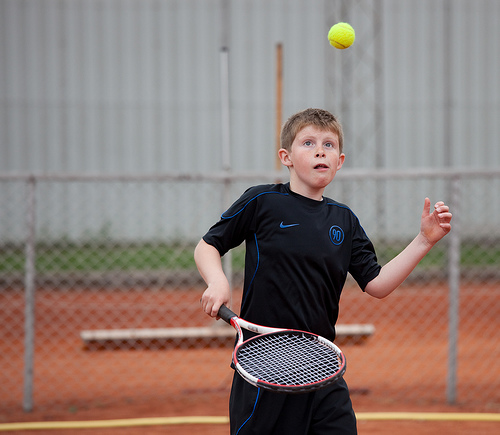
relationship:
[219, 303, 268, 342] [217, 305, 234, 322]
handle has tape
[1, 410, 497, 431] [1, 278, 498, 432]
line on ground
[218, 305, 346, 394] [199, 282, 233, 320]
racket in hand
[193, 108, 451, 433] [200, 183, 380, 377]
boy wearing a shirt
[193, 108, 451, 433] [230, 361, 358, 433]
boy wearing shorts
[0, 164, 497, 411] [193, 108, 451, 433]
fence behind boy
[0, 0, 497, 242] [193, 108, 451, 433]
building behind boy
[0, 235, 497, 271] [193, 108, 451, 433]
grass behind boy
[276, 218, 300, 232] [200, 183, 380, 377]
logo on shirt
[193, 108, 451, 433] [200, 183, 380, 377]
boy wearing shirt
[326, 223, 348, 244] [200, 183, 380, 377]
number on shirt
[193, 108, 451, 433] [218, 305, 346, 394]
boy holding racket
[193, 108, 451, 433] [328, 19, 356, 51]
boy looking at ball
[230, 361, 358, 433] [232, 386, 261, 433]
shorts have stripe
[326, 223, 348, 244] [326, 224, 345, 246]
number in a circle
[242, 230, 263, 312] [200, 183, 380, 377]
stripe on shirt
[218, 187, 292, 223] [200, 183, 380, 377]
stripe on shirt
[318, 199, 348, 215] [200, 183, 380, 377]
stripe on shirt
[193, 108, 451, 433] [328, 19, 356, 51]
boy trying to hit ball